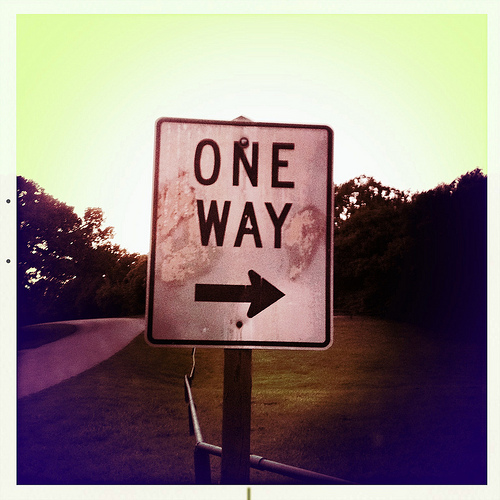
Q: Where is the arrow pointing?
A: To the right.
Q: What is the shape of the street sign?
A: Rectangle.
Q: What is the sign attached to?
A: Metal pole.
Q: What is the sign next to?
A: Metal fencing.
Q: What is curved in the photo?
A: Road.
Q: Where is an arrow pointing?
A: To the right.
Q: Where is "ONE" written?
A: On a sign.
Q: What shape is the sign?
A: Rectangular.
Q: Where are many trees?
A: In the distance.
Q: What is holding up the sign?
A: A post.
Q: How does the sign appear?
A: Dirty.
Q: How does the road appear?
A: Curved.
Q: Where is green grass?
A: Next to the road.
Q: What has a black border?
A: The sign.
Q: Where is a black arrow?
A: On sign.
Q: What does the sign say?
A: One way.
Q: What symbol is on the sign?
A: Arrow.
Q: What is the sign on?
A: A post.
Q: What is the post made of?
A: Wood.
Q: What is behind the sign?
A: A fence.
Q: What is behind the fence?
A: Grass.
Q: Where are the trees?
A: Behind the sign.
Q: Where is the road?
A: To the left.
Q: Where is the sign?
A: Next to the road.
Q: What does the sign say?
A: One way.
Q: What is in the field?
A: A fence.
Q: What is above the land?
A: The sky.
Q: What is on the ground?
A: Grass.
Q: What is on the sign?
A: An arrow.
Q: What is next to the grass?
A: Trees.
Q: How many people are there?
A: 0.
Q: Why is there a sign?
A: For traffic safety.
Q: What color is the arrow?
A: Black.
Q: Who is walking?
A: No one.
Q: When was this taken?
A: During the day.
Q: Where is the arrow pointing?
A: Right.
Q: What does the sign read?
A: One way.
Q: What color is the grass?
A: Green.